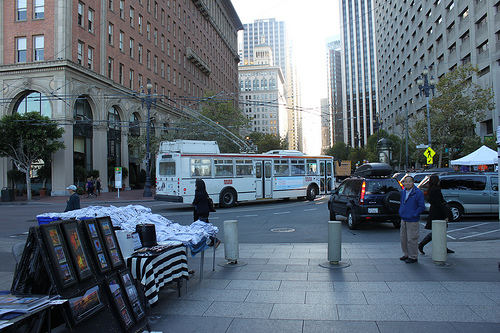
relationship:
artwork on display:
[34, 230, 147, 327] [24, 229, 179, 327]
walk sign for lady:
[420, 142, 440, 160] [418, 174, 455, 255]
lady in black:
[425, 175, 457, 254] [427, 184, 448, 235]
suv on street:
[327, 162, 406, 229] [13, 199, 499, 242]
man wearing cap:
[67, 184, 81, 211] [65, 183, 79, 192]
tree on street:
[1, 111, 53, 203] [13, 199, 499, 242]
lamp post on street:
[136, 78, 161, 200] [13, 199, 499, 242]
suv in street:
[326, 175, 406, 227] [13, 199, 499, 242]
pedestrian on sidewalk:
[397, 177, 426, 265] [192, 247, 499, 333]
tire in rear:
[220, 190, 237, 207] [159, 137, 249, 212]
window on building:
[74, 39, 88, 68] [8, 1, 252, 196]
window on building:
[88, 44, 96, 69] [8, 1, 252, 196]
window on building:
[108, 53, 115, 78] [8, 1, 252, 196]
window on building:
[120, 63, 126, 84] [8, 1, 252, 196]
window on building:
[130, 68, 137, 96] [8, 1, 252, 196]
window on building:
[139, 72, 145, 91] [8, 1, 252, 196]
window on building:
[75, 0, 86, 30] [8, 1, 252, 196]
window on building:
[91, 7, 98, 33] [8, 1, 252, 196]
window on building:
[107, 20, 116, 47] [8, 1, 252, 196]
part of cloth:
[136, 256, 189, 274] [126, 252, 199, 288]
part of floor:
[248, 263, 282, 294] [192, 247, 499, 333]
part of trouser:
[403, 219, 421, 259] [400, 217, 418, 262]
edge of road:
[247, 239, 324, 245] [13, 199, 499, 242]